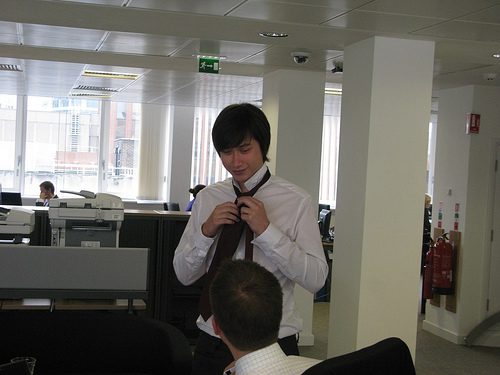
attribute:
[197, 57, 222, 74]
directional sign — green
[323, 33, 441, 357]
structure beam — white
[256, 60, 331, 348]
structure beam — white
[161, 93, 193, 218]
structure beam — white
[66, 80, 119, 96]
vent — metal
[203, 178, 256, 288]
necktie — black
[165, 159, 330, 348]
shirt — white, long sleeve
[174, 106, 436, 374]
man — wearing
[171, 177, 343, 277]
shirt — white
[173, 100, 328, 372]
man — young, wearing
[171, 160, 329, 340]
white shirt — dress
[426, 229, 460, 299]
fire extinguisher — red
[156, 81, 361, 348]
man — wearing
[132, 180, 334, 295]
shirt — white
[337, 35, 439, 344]
column — tall, white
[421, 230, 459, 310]
extinguisher — red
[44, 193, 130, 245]
copy machine — large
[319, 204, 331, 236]
monitor — black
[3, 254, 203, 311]
partition — grey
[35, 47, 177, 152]
vent — metal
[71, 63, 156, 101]
vent — metal